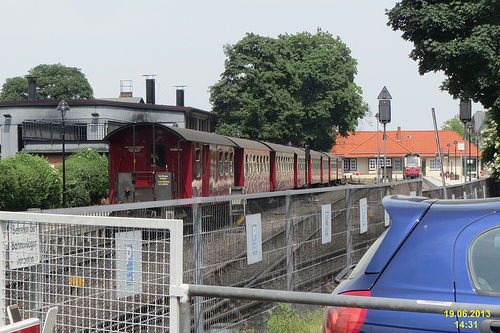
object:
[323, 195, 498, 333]
car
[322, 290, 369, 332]
tail light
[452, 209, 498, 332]
door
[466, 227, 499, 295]
window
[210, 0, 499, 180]
tree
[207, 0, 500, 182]
leaves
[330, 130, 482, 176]
building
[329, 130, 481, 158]
roof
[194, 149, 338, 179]
window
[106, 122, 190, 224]
back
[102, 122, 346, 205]
car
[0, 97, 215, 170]
house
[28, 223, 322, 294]
tracks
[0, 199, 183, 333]
fence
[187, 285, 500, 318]
railing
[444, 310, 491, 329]
numbers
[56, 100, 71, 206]
street light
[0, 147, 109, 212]
bushes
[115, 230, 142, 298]
sign